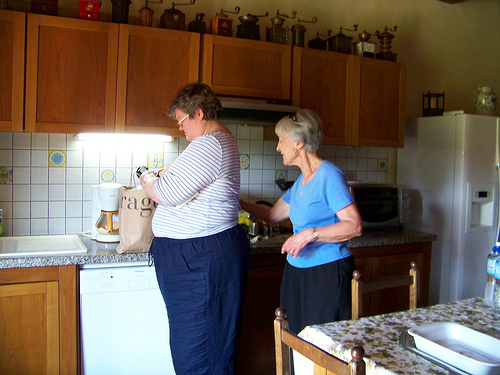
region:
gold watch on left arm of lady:
[307, 221, 323, 246]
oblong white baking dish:
[393, 317, 490, 372]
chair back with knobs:
[252, 291, 368, 372]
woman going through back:
[142, 86, 242, 362]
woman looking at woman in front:
[252, 107, 367, 317]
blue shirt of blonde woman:
[272, 155, 357, 270]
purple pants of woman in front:
[142, 222, 247, 372]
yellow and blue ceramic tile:
[40, 140, 67, 172]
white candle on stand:
[92, 176, 118, 209]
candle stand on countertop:
[94, 210, 124, 240]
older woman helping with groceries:
[262, 96, 342, 311]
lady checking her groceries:
[156, 69, 246, 272]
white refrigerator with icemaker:
[390, 102, 499, 242]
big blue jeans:
[163, 242, 231, 370]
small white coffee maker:
[72, 169, 137, 251]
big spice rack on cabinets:
[167, 0, 419, 85]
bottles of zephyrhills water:
[463, 237, 498, 292]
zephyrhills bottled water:
[460, 218, 498, 268]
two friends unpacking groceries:
[113, 75, 385, 296]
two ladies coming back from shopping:
[106, 67, 413, 310]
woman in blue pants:
[111, 54, 281, 374]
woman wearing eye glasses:
[141, 84, 228, 168]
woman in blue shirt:
[262, 111, 369, 283]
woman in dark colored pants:
[274, 115, 352, 326]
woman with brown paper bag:
[102, 117, 236, 264]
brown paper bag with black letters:
[104, 152, 166, 259]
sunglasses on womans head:
[264, 101, 328, 166]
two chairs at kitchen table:
[265, 211, 497, 362]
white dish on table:
[355, 290, 489, 374]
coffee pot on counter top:
[92, 175, 129, 257]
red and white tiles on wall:
[5, 172, 75, 212]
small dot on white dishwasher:
[98, 268, 133, 285]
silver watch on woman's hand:
[303, 226, 331, 246]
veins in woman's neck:
[284, 127, 326, 181]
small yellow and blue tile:
[40, 139, 81, 186]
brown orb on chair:
[334, 266, 383, 300]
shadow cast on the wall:
[378, 27, 476, 116]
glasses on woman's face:
[161, 105, 228, 154]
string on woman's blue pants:
[128, 225, 188, 268]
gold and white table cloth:
[341, 321, 433, 373]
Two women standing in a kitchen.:
[30, 58, 480, 367]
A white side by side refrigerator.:
[414, 105, 499, 303]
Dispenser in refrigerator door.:
[460, 167, 495, 237]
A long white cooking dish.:
[408, 312, 497, 374]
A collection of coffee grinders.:
[16, 1, 408, 60]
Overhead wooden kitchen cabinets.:
[2, 16, 411, 151]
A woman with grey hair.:
[262, 94, 370, 323]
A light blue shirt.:
[272, 162, 357, 264]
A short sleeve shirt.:
[268, 158, 364, 277]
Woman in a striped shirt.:
[139, 80, 264, 287]